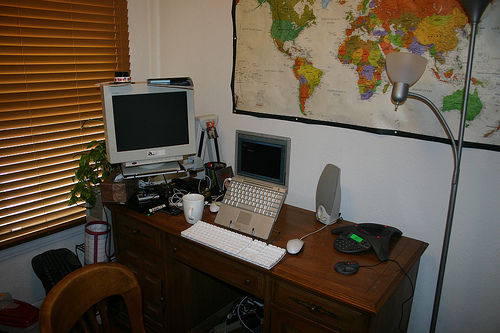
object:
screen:
[112, 91, 191, 153]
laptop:
[213, 129, 292, 241]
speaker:
[315, 162, 341, 225]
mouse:
[284, 238, 304, 255]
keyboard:
[179, 219, 287, 270]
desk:
[103, 176, 429, 332]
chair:
[37, 261, 147, 332]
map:
[230, 0, 499, 152]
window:
[1, 1, 131, 249]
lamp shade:
[383, 52, 429, 86]